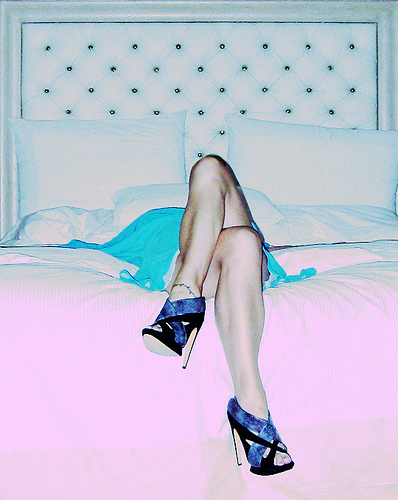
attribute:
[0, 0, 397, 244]
headboard — white, padded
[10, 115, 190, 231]
pillow — white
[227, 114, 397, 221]
pillow — white, slanted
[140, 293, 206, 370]
shoe — blue, black, heeled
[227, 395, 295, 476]
shoe — blue, black, heeled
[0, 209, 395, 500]
cover — stripped, pink, white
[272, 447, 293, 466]
toes — painted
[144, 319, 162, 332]
toes — painted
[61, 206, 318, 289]
dress — blue, aqua